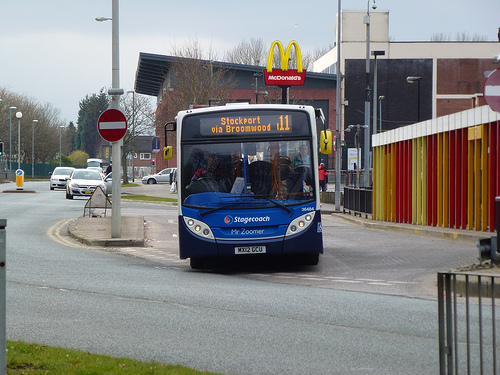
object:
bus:
[169, 101, 330, 272]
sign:
[261, 37, 313, 90]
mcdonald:
[267, 73, 302, 82]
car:
[63, 162, 110, 199]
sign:
[80, 185, 113, 212]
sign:
[93, 105, 132, 143]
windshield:
[186, 139, 318, 210]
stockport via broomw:
[207, 114, 272, 135]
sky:
[0, 0, 489, 91]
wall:
[372, 140, 495, 234]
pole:
[101, 1, 127, 239]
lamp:
[13, 111, 27, 121]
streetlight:
[94, 16, 108, 25]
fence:
[428, 270, 498, 375]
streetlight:
[404, 74, 416, 83]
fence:
[33, 161, 54, 179]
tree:
[75, 90, 101, 152]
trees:
[5, 96, 29, 156]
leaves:
[90, 100, 95, 105]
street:
[101, 278, 286, 362]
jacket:
[315, 167, 331, 183]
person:
[317, 161, 331, 193]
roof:
[334, 10, 499, 61]